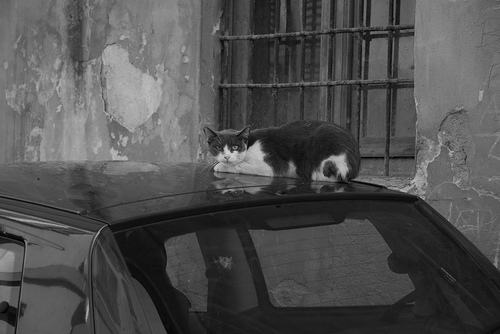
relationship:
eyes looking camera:
[214, 144, 295, 162] [0, 54, 481, 316]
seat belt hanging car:
[200, 239, 240, 316] [2, 157, 497, 332]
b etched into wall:
[478, 12, 498, 55] [3, 1, 496, 307]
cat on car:
[202, 120, 362, 188] [2, 157, 497, 332]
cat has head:
[202, 120, 362, 188] [191, 125, 258, 160]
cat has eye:
[202, 120, 362, 188] [231, 143, 240, 150]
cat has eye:
[202, 120, 362, 188] [215, 143, 223, 148]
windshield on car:
[194, 219, 426, 291] [7, 156, 455, 315]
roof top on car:
[32, 171, 264, 235] [1, 150, 482, 322]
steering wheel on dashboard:
[386, 287, 448, 329] [306, 301, 468, 331]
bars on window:
[213, 21, 418, 42] [213, 5, 413, 176]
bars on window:
[222, 74, 417, 90] [213, 5, 413, 176]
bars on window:
[382, 2, 397, 177] [213, 5, 413, 176]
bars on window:
[345, 4, 360, 131] [213, 5, 413, 176]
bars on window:
[267, 0, 282, 122] [213, 5, 413, 176]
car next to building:
[39, 182, 259, 324] [8, 4, 484, 260]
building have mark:
[2, 2, 498, 330] [98, 42, 163, 129]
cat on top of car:
[217, 120, 357, 188] [4, 159, 484, 307]